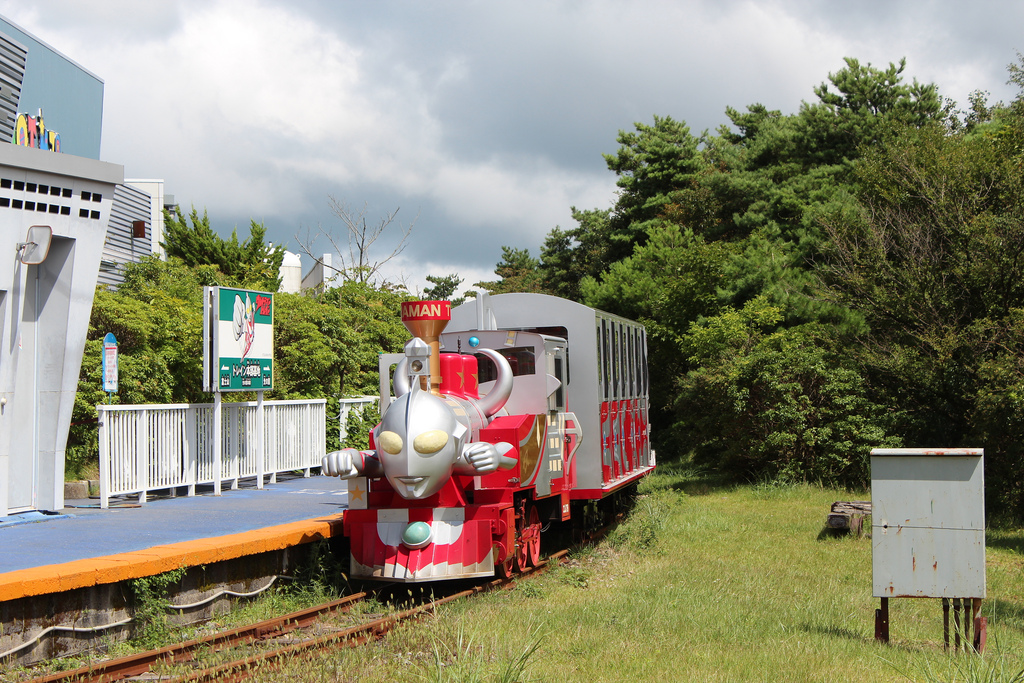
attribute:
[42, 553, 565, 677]
train tracks — old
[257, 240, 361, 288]
building — tall, white, in the distance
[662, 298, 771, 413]
leaves — green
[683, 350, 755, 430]
leaves — green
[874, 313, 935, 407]
leaves — green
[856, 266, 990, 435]
leaves — green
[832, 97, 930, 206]
leaves — green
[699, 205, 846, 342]
leaves — green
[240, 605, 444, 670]
weeds — few, overgrown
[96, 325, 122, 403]
sign — small, blue, white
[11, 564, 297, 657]
cable — cement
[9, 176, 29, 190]
window — glass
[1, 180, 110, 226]
windows — glass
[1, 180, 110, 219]
window — glass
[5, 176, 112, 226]
window — glass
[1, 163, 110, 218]
window — glass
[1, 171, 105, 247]
window — glass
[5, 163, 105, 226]
window — glass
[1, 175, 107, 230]
window — glass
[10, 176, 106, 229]
window — glass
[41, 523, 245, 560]
line — yellow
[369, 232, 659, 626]
train — silver , red 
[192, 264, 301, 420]
sign — white  , green 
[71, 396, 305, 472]
railing — white  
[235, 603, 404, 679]
tracks — train 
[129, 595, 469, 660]
tracks — train 